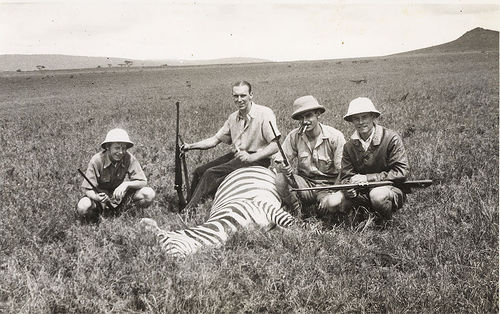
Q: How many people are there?
A: Four.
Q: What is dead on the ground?
A: A zebra.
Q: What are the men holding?
A: Guns.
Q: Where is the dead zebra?
A: In the grass.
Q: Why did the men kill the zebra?
A: To hunt.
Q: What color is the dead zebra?
A: Black and white.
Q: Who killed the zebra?
A: The men with the guns.